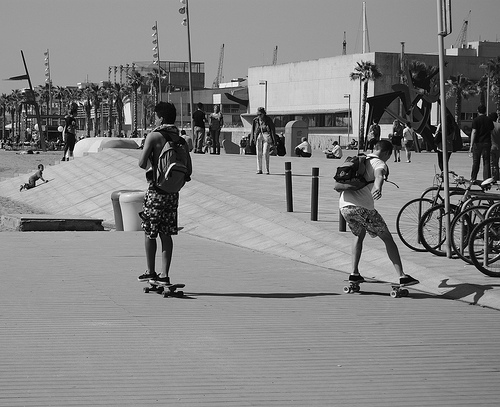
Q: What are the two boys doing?
A: Skate boarding.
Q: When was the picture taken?
A: During the day.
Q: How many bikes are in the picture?
A: Four.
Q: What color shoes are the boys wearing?
A: Black.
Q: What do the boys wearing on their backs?
A: Back packs.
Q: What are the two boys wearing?
A: Shorts.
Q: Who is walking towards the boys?
A: A women.